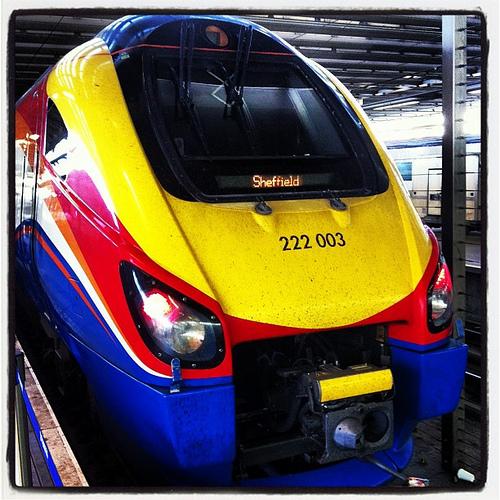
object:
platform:
[11, 336, 89, 488]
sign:
[219, 172, 336, 187]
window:
[42, 93, 72, 185]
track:
[11, 304, 483, 492]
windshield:
[113, 0, 392, 206]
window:
[113, 23, 390, 197]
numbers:
[276, 228, 350, 253]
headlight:
[118, 259, 224, 369]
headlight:
[427, 255, 452, 332]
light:
[112, 271, 297, 389]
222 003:
[270, 220, 356, 255]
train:
[12, 14, 472, 484]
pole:
[435, 16, 469, 330]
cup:
[456, 468, 475, 482]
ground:
[14, 327, 486, 493]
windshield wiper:
[216, 15, 268, 134]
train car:
[387, 137, 484, 225]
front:
[85, 12, 469, 485]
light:
[415, 253, 469, 346]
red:
[79, 213, 116, 261]